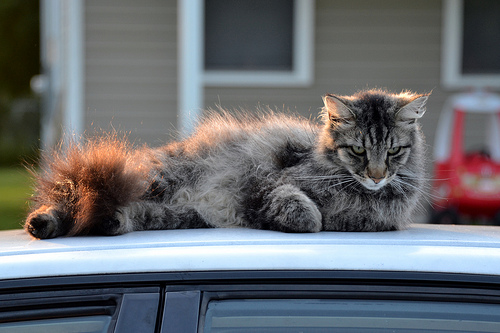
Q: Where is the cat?
A: On top of the car.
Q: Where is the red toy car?
A: Near the house.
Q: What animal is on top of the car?
A: Cat.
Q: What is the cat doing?
A: Laying on top of the car.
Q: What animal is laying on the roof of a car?
A: A cat.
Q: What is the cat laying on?
A: The roof of a car.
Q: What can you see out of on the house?
A: Windows.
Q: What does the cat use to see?
A: Eyes.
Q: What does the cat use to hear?
A: Ears.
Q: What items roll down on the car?
A: Windows.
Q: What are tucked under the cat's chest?
A: Paws.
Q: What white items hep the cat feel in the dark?
A: Whiskers.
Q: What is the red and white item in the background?
A: A toy car.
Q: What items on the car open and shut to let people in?
A: Doors.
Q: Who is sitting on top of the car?
A: A cat.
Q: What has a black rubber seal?
A: Window.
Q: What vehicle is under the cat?
A: Car.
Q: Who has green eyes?
A: Cat.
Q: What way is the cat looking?
A: Down.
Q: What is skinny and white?
A: Whiskers.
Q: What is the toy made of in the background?
A: Plastic.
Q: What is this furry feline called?
A: Cat.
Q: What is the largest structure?
A: House.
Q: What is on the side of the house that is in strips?
A: Siding.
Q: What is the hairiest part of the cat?
A: Tail.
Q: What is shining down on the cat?
A: Sunlight.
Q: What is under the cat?
A: Vehicle.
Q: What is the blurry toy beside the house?
A: Little car.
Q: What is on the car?
A: Cat.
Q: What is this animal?
A: Cat.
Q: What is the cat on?
A: Car.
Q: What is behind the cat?
A: House.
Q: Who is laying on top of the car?
A: A cat.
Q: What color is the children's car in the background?
A: Red.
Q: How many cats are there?
A: 1.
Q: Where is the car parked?
A: In front of the house.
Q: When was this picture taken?
A: Daytime.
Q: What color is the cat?
A: Gray and black.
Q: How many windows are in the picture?
A: 4.